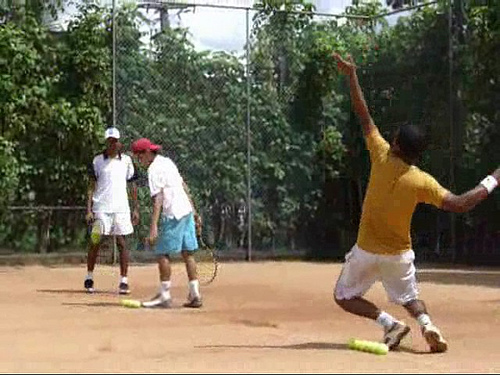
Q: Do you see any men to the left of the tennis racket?
A: Yes, there is a man to the left of the tennis racket.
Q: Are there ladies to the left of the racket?
A: No, there is a man to the left of the racket.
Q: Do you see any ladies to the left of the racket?
A: No, there is a man to the left of the racket.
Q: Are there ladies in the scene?
A: No, there are no ladies.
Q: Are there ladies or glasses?
A: No, there are no ladies or glasses.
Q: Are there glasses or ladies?
A: No, there are no ladies or glasses.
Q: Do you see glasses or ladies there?
A: No, there are no ladies or glasses.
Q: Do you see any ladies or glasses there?
A: No, there are no ladies or glasses.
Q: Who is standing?
A: The man is standing.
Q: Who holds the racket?
A: The man holds the tennis racket.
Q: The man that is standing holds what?
A: The man holds the racket.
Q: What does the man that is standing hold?
A: The man holds the racket.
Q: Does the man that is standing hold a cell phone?
A: No, the man holds the racket.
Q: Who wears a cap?
A: The man wears a cap.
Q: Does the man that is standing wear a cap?
A: Yes, the man wears a cap.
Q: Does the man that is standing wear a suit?
A: No, the man wears a cap.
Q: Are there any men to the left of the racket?
A: Yes, there is a man to the left of the racket.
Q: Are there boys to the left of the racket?
A: No, there is a man to the left of the racket.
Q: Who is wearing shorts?
A: The man is wearing shorts.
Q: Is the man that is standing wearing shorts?
A: Yes, the man is wearing shorts.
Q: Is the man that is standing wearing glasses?
A: No, the man is wearing shorts.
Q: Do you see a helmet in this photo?
A: No, there are no helmets.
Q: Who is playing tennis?
A: The man is playing tennis.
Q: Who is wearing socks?
A: The man is wearing socks.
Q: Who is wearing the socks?
A: The man is wearing socks.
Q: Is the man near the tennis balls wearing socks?
A: Yes, the man is wearing socks.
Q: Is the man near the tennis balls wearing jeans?
A: No, the man is wearing socks.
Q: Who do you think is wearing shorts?
A: The man is wearing shorts.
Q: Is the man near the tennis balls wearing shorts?
A: Yes, the man is wearing shorts.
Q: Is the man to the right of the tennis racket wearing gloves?
A: No, the man is wearing shorts.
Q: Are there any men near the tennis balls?
A: Yes, there is a man near the tennis balls.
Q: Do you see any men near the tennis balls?
A: Yes, there is a man near the tennis balls.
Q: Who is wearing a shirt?
A: The man is wearing a shirt.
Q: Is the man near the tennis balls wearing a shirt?
A: Yes, the man is wearing a shirt.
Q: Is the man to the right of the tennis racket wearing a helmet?
A: No, the man is wearing a shirt.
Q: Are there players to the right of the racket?
A: No, there is a man to the right of the racket.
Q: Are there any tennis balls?
A: Yes, there are tennis balls.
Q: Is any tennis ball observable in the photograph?
A: Yes, there are tennis balls.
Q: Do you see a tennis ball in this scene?
A: Yes, there are tennis balls.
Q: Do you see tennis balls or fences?
A: Yes, there are tennis balls.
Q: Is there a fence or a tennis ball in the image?
A: Yes, there are tennis balls.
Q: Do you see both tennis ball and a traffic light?
A: No, there are tennis balls but no traffic lights.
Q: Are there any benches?
A: No, there are no benches.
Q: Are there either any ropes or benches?
A: No, there are no benches or ropes.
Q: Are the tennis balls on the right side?
A: Yes, the tennis balls are on the right of the image.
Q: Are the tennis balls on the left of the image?
A: No, the tennis balls are on the right of the image.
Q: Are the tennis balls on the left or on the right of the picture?
A: The tennis balls are on the right of the image.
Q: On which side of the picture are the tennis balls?
A: The tennis balls are on the right of the image.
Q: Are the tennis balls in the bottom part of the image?
A: Yes, the tennis balls are in the bottom of the image.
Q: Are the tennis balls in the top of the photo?
A: No, the tennis balls are in the bottom of the image.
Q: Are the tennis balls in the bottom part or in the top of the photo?
A: The tennis balls are in the bottom of the image.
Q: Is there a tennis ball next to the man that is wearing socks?
A: Yes, there are tennis balls next to the man.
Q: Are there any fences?
A: Yes, there is a fence.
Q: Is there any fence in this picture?
A: Yes, there is a fence.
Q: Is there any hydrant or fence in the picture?
A: Yes, there is a fence.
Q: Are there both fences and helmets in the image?
A: No, there is a fence but no helmets.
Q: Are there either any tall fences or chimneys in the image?
A: Yes, there is a tall fence.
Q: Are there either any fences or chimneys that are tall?
A: Yes, the fence is tall.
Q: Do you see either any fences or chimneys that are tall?
A: Yes, the fence is tall.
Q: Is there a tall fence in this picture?
A: Yes, there is a tall fence.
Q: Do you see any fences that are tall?
A: Yes, there is a fence that is tall.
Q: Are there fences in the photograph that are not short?
A: Yes, there is a tall fence.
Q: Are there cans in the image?
A: No, there are no cans.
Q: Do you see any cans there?
A: No, there are no cans.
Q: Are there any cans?
A: No, there are no cans.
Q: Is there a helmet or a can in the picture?
A: No, there are no cans or helmets.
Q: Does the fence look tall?
A: Yes, the fence is tall.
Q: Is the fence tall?
A: Yes, the fence is tall.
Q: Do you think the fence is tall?
A: Yes, the fence is tall.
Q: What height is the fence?
A: The fence is tall.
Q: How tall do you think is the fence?
A: The fence is tall.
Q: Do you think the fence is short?
A: No, the fence is tall.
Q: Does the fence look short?
A: No, the fence is tall.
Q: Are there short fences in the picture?
A: No, there is a fence but it is tall.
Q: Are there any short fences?
A: No, there is a fence but it is tall.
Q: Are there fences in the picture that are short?
A: No, there is a fence but it is tall.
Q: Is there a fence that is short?
A: No, there is a fence but it is tall.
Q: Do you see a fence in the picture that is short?
A: No, there is a fence but it is tall.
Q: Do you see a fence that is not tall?
A: No, there is a fence but it is tall.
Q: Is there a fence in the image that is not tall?
A: No, there is a fence but it is tall.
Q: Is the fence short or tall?
A: The fence is tall.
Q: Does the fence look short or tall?
A: The fence is tall.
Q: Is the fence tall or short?
A: The fence is tall.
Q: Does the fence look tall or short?
A: The fence is tall.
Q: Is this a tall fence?
A: Yes, this is a tall fence.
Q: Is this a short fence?
A: No, this is a tall fence.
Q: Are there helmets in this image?
A: No, there are no helmets.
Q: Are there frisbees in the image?
A: No, there are no frisbees.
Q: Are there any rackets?
A: Yes, there is a racket.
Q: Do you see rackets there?
A: Yes, there is a racket.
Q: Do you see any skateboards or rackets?
A: Yes, there is a racket.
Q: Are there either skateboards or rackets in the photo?
A: Yes, there is a racket.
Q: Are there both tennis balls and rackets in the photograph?
A: Yes, there are both a racket and a tennis ball.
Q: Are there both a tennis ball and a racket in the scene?
A: Yes, there are both a racket and a tennis ball.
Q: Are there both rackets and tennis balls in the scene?
A: Yes, there are both a racket and a tennis ball.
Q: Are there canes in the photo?
A: No, there are no canes.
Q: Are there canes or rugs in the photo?
A: No, there are no canes or rugs.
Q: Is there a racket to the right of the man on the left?
A: Yes, there is a racket to the right of the man.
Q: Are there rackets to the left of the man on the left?
A: No, the racket is to the right of the man.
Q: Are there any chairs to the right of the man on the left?
A: No, there is a racket to the right of the man.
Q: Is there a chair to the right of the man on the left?
A: No, there is a racket to the right of the man.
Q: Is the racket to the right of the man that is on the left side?
A: Yes, the racket is to the right of the man.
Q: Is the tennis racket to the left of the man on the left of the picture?
A: No, the tennis racket is to the right of the man.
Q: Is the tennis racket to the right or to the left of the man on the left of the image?
A: The tennis racket is to the right of the man.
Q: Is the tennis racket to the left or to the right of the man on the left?
A: The tennis racket is to the right of the man.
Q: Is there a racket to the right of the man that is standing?
A: Yes, there is a racket to the right of the man.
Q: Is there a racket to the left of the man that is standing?
A: No, the racket is to the right of the man.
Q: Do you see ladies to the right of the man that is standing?
A: No, there is a racket to the right of the man.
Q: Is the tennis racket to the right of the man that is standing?
A: Yes, the tennis racket is to the right of the man.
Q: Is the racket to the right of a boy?
A: No, the racket is to the right of the man.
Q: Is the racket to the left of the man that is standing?
A: No, the racket is to the right of the man.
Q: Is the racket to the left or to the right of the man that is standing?
A: The racket is to the right of the man.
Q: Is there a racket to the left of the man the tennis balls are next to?
A: Yes, there is a racket to the left of the man.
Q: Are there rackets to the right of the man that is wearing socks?
A: No, the racket is to the left of the man.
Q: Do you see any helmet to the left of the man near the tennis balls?
A: No, there is a racket to the left of the man.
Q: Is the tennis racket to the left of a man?
A: Yes, the tennis racket is to the left of a man.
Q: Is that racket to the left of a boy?
A: No, the racket is to the left of a man.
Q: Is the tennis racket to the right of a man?
A: No, the tennis racket is to the left of a man.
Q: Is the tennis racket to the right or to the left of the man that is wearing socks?
A: The tennis racket is to the left of the man.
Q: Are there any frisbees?
A: No, there are no frisbees.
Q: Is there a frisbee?
A: No, there are no frisbees.